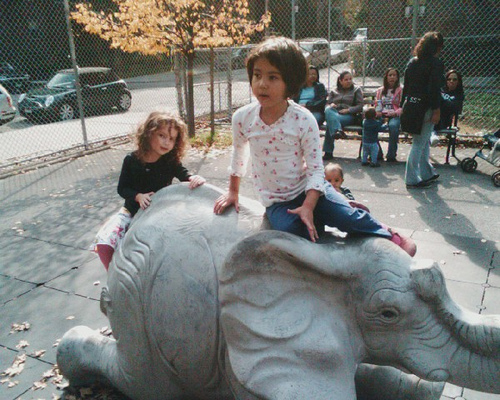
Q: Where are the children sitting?
A: On an elephant statue.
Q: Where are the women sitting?
A: On a bench.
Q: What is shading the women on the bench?
A: A tree.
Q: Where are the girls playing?
A: On an elephant statue.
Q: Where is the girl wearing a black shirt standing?
A: Behind the elephant statue.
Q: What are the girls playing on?
A: An elephant statue.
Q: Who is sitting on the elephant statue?
A: Two girls.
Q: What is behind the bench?
A: A fence.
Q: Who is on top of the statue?
A: A brown-haired girl in a flowered shirt.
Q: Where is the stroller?
A: To the right of the bench.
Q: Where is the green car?
A: On the road.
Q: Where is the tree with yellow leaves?
A: In the corner near the fence.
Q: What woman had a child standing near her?
A: The one in the pink sweater.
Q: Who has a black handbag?
A: The woman standing by the bench.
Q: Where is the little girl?
A: On top of the statue.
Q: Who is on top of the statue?
A: A little girl.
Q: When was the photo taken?
A: Daylight hours.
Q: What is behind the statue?
A: A tree with orange leaves.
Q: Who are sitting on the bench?
A: A group of women.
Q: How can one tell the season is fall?
A: The tree leaves are not green.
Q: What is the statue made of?
A: Concrete.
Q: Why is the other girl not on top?
A: Not sure she can climb on top.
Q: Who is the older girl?
A: The one on top of the elephant.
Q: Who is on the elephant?
A: Children.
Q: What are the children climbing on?
A: An elephant statue.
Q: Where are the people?
A: In a park.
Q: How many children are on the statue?
A: 2.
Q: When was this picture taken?
A: Daytime.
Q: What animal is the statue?
A: Elephant.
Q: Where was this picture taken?
A: Playground.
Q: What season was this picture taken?
A: Fall.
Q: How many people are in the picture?
A: 9.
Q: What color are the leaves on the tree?
A: Yellow.